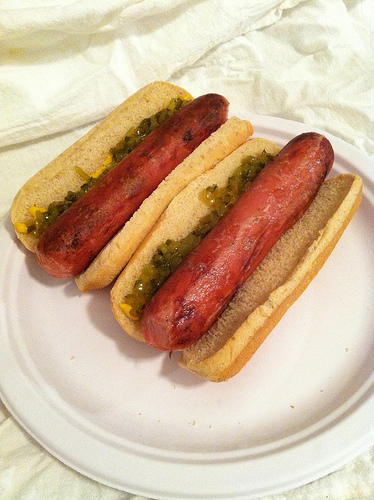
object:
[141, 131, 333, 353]
hot dog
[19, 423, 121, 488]
mat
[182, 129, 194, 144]
char mark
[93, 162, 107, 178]
mustard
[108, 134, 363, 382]
sandwich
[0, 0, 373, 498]
white tablecloth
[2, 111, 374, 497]
paper plate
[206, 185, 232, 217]
relish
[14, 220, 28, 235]
dob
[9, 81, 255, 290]
bun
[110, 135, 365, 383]
bun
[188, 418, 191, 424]
crumbs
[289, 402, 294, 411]
crumbs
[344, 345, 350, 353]
crumbs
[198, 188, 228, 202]
paste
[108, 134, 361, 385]
bread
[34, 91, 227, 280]
hotdog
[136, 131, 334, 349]
hotdog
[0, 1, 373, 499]
table